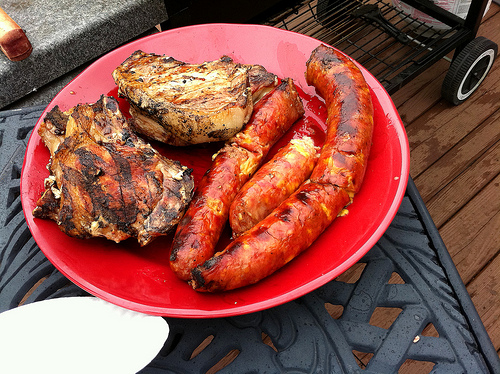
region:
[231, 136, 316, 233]
Delicious looking red sausage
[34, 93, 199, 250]
delicious looking grilled chicken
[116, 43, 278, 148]
delicious looking grilled chicken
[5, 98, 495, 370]
black steel decorated table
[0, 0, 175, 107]
grey granite counter top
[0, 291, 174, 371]
white paper plate new plate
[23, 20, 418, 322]
Big red plate with food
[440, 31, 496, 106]
Black and white wheel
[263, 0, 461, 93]
Black wire basket near wheel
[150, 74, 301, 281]
delicious looking red sausage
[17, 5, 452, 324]
the plate is on the table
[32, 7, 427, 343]
food is on the plate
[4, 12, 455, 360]
the plate is red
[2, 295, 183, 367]
a plate to the left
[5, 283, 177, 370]
the plate is white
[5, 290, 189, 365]
the plate is made of paper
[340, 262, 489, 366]
the table is black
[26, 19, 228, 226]
pork chops are on the plate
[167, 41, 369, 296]
sausages are on the plate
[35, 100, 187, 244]
cooked meat on the plate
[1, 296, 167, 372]
a white paper plate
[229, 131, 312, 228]
sausage cut in half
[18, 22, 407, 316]
round red plate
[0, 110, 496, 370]
black metal table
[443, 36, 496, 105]
black wheel with a white stripe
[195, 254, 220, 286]
burn mark on the sausage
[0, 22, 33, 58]
wooden handle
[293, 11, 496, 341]
brown wooden patio deck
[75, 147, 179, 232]
grill marks on the food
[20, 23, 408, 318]
Round, red plate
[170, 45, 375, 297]
Three grilled and cut up sausages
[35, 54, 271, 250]
Two Grilled porkchops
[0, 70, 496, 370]
Large, black, metal outdoor table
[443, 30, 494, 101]
Black and white grill tired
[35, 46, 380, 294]
Different grilled meat types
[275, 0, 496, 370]
Brown, wet, wooden deck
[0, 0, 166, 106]
Granite counter top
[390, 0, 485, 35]
Propane tank for grill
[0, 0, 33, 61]
Wooden tool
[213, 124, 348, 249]
Sausages on the plate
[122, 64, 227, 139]
Meat in the photo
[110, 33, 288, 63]
A red plate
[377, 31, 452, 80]
A cart in the photo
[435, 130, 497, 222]
A wooden floor in the photo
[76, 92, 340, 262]
Food on the plate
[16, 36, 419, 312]
A plate with sausage and meat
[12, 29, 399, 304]
A red plate with food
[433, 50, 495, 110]
Wheel of a cart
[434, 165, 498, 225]
Wooden floor in the picture